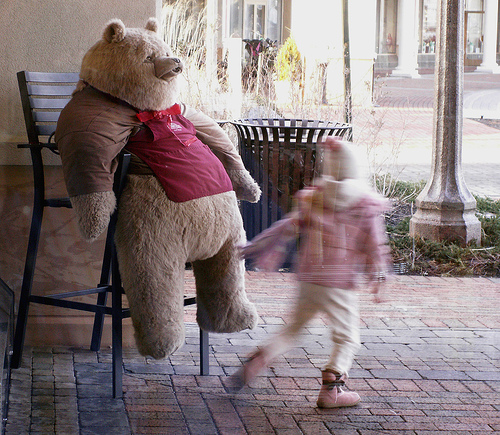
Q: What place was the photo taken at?
A: It was taken at the sidewalk.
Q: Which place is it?
A: It is a sidewalk.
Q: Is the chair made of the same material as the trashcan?
A: Yes, both the chair and the trashcan are made of metal.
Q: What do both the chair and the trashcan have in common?
A: The material, both the chair and the trashcan are metallic.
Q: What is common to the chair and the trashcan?
A: The material, both the chair and the trashcan are metallic.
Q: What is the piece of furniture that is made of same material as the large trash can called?
A: The piece of furniture is a chair.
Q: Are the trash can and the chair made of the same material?
A: Yes, both the trash can and the chair are made of metal.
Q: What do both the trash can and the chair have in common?
A: The material, both the trash can and the chair are metallic.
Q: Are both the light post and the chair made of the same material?
A: No, the light post is made of cement and the chair is made of metal.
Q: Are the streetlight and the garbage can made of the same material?
A: No, the streetlight is made of cement and the garbage can is made of metal.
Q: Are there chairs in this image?
A: Yes, there is a chair.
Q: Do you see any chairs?
A: Yes, there is a chair.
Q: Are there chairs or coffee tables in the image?
A: Yes, there is a chair.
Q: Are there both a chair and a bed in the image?
A: No, there is a chair but no beds.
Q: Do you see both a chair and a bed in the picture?
A: No, there is a chair but no beds.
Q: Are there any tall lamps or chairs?
A: Yes, there is a tall chair.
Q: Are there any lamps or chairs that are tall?
A: Yes, the chair is tall.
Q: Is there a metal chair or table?
A: Yes, there is a metal chair.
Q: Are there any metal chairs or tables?
A: Yes, there is a metal chair.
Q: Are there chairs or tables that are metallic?
A: Yes, the chair is metallic.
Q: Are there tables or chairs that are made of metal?
A: Yes, the chair is made of metal.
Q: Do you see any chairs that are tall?
A: Yes, there is a tall chair.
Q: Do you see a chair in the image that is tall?
A: Yes, there is a chair that is tall.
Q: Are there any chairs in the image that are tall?
A: Yes, there is a chair that is tall.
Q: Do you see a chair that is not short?
A: Yes, there is a tall chair.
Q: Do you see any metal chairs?
A: Yes, there is a metal chair.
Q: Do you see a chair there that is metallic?
A: Yes, there is a chair that is metallic.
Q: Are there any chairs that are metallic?
A: Yes, there is a chair that is metallic.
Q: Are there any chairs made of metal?
A: Yes, there is a chair that is made of metal.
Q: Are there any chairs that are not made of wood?
A: Yes, there is a chair that is made of metal.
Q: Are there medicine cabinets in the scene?
A: No, there are no medicine cabinets.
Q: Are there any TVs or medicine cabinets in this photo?
A: No, there are no medicine cabinets or tvs.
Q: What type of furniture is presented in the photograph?
A: The furniture is a chair.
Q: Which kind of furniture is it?
A: The piece of furniture is a chair.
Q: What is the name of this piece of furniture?
A: That is a chair.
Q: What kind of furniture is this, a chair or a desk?
A: That is a chair.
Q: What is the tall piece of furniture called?
A: The piece of furniture is a chair.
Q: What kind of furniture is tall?
A: The furniture is a chair.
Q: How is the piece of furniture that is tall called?
A: The piece of furniture is a chair.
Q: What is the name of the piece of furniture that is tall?
A: The piece of furniture is a chair.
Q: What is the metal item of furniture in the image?
A: The piece of furniture is a chair.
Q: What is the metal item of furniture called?
A: The piece of furniture is a chair.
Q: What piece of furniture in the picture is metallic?
A: The piece of furniture is a chair.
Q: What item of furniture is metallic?
A: The piece of furniture is a chair.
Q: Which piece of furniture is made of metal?
A: The piece of furniture is a chair.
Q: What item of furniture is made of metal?
A: The piece of furniture is a chair.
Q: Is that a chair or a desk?
A: That is a chair.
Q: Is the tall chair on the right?
A: No, the chair is on the left of the image.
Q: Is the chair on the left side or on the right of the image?
A: The chair is on the left of the image.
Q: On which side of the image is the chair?
A: The chair is on the left of the image.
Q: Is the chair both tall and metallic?
A: Yes, the chair is tall and metallic.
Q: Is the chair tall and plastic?
A: No, the chair is tall but metallic.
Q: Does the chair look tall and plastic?
A: No, the chair is tall but metallic.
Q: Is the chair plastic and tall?
A: No, the chair is tall but metallic.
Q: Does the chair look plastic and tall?
A: No, the chair is tall but metallic.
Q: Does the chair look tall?
A: Yes, the chair is tall.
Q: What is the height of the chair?
A: The chair is tall.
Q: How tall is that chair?
A: The chair is tall.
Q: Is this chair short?
A: No, the chair is tall.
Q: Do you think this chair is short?
A: No, the chair is tall.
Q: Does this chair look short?
A: No, the chair is tall.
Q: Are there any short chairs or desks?
A: No, there is a chair but it is tall.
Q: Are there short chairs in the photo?
A: No, there is a chair but it is tall.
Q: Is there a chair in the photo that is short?
A: No, there is a chair but it is tall.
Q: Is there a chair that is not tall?
A: No, there is a chair but it is tall.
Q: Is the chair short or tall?
A: The chair is tall.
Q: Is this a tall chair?
A: Yes, this is a tall chair.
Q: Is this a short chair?
A: No, this is a tall chair.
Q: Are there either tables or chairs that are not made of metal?
A: No, there is a chair but it is made of metal.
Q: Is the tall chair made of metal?
A: Yes, the chair is made of metal.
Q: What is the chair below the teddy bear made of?
A: The chair is made of metal.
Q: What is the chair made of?
A: The chair is made of metal.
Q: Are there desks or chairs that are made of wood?
A: No, there is a chair but it is made of metal.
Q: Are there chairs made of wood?
A: No, there is a chair but it is made of metal.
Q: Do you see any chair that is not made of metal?
A: No, there is a chair but it is made of metal.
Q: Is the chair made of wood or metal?
A: The chair is made of metal.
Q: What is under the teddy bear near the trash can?
A: The chair is under the teddy bear.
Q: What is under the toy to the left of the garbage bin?
A: The chair is under the teddy bear.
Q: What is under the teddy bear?
A: The chair is under the teddy bear.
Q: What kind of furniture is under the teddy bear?
A: The piece of furniture is a chair.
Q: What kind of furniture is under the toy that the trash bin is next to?
A: The piece of furniture is a chair.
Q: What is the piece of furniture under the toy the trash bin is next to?
A: The piece of furniture is a chair.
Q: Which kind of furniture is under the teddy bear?
A: The piece of furniture is a chair.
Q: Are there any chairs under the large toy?
A: Yes, there is a chair under the teddy bear.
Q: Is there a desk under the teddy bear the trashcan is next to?
A: No, there is a chair under the teddy bear.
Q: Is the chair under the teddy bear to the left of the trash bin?
A: Yes, the chair is under the teddy bear.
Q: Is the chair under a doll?
A: No, the chair is under the teddy bear.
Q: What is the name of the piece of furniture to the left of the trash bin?
A: The piece of furniture is a chair.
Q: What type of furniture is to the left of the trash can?
A: The piece of furniture is a chair.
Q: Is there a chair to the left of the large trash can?
A: Yes, there is a chair to the left of the trashcan.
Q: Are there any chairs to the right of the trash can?
A: No, the chair is to the left of the trash can.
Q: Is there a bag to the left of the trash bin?
A: No, there is a chair to the left of the trash bin.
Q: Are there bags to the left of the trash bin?
A: No, there is a chair to the left of the trash bin.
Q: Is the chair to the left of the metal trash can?
A: Yes, the chair is to the left of the garbage can.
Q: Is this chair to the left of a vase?
A: No, the chair is to the left of the garbage can.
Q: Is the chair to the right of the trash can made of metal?
A: No, the chair is to the left of the trash can.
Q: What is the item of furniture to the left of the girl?
A: The piece of furniture is a chair.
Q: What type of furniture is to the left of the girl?
A: The piece of furniture is a chair.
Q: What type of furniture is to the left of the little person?
A: The piece of furniture is a chair.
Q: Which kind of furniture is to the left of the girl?
A: The piece of furniture is a chair.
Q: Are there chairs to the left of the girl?
A: Yes, there is a chair to the left of the girl.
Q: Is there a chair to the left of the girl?
A: Yes, there is a chair to the left of the girl.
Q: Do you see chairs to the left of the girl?
A: Yes, there is a chair to the left of the girl.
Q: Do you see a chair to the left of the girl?
A: Yes, there is a chair to the left of the girl.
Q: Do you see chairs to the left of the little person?
A: Yes, there is a chair to the left of the girl.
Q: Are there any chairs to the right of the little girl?
A: No, the chair is to the left of the girl.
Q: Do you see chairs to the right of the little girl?
A: No, the chair is to the left of the girl.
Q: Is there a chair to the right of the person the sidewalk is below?
A: No, the chair is to the left of the girl.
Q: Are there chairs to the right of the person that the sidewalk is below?
A: No, the chair is to the left of the girl.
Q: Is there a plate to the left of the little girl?
A: No, there is a chair to the left of the girl.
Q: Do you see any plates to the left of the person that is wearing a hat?
A: No, there is a chair to the left of the girl.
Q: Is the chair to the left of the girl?
A: Yes, the chair is to the left of the girl.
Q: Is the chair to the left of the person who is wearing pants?
A: Yes, the chair is to the left of the girl.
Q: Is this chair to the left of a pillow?
A: No, the chair is to the left of the girl.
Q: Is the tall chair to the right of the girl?
A: No, the chair is to the left of the girl.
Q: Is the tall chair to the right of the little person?
A: No, the chair is to the left of the girl.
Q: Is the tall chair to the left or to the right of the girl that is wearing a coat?
A: The chair is to the left of the girl.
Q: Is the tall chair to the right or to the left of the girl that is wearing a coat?
A: The chair is to the left of the girl.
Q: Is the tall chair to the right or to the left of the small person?
A: The chair is to the left of the girl.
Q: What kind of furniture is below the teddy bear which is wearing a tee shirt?
A: The piece of furniture is a chair.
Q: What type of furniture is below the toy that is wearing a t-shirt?
A: The piece of furniture is a chair.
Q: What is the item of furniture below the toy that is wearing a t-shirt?
A: The piece of furniture is a chair.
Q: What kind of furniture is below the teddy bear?
A: The piece of furniture is a chair.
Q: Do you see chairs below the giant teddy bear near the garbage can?
A: Yes, there is a chair below the teddy bear.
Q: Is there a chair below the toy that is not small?
A: Yes, there is a chair below the teddy bear.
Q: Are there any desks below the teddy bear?
A: No, there is a chair below the teddy bear.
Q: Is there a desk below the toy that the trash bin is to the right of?
A: No, there is a chair below the teddy bear.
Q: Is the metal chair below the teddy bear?
A: Yes, the chair is below the teddy bear.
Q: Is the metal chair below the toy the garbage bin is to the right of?
A: Yes, the chair is below the teddy bear.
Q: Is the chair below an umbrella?
A: No, the chair is below the teddy bear.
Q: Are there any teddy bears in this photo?
A: Yes, there is a teddy bear.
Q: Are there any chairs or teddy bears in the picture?
A: Yes, there is a teddy bear.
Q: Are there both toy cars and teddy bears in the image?
A: No, there is a teddy bear but no toy cars.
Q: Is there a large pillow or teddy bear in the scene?
A: Yes, there is a large teddy bear.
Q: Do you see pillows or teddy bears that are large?
A: Yes, the teddy bear is large.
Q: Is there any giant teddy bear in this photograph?
A: Yes, there is a giant teddy bear.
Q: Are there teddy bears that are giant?
A: Yes, there is a teddy bear that is giant.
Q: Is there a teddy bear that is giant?
A: Yes, there is a teddy bear that is giant.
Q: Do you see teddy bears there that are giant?
A: Yes, there is a teddy bear that is giant.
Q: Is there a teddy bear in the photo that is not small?
A: Yes, there is a giant teddy bear.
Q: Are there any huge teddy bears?
A: Yes, there is a huge teddy bear.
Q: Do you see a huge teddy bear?
A: Yes, there is a huge teddy bear.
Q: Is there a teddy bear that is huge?
A: Yes, there is a teddy bear that is huge.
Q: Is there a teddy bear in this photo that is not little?
A: Yes, there is a huge teddy bear.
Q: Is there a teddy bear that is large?
A: Yes, there is a large teddy bear.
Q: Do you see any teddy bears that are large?
A: Yes, there is a teddy bear that is large.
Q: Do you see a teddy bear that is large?
A: Yes, there is a teddy bear that is large.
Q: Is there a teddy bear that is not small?
A: Yes, there is a large teddy bear.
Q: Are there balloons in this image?
A: No, there are no balloons.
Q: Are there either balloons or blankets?
A: No, there are no balloons or blankets.